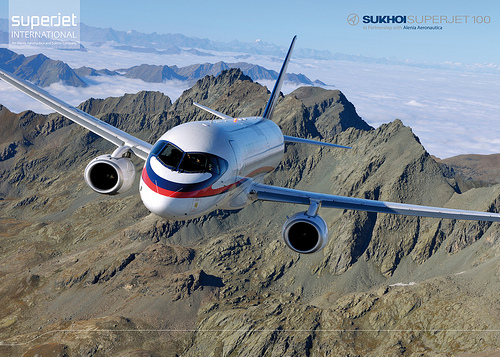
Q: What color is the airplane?
A: White.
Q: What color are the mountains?
A: Brown.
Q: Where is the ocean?
A: Behind mountains.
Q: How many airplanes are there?
A: One.